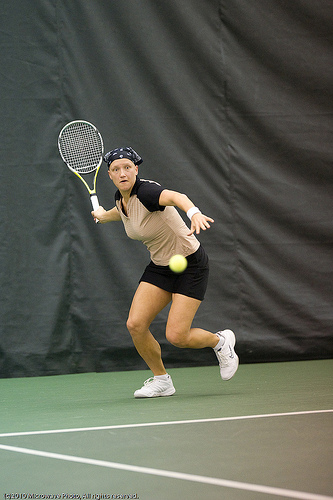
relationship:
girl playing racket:
[91, 147, 239, 397] [57, 119, 105, 224]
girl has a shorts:
[91, 147, 239, 397] [139, 245, 208, 299]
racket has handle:
[58, 119, 104, 221] [90, 195, 100, 222]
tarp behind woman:
[0, 0, 333, 377] [90, 146, 239, 397]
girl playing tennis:
[91, 147, 239, 397] [36, 79, 298, 445]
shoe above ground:
[212, 325, 239, 383] [1, 399, 332, 498]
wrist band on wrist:
[183, 207, 201, 220] [182, 205, 200, 221]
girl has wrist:
[91, 147, 239, 397] [182, 205, 200, 221]